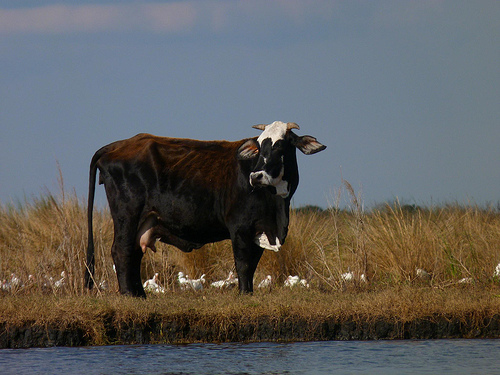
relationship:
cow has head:
[83, 122, 329, 301] [242, 121, 327, 186]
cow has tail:
[83, 122, 329, 301] [83, 145, 99, 294]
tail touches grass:
[83, 145, 99, 294] [0, 199, 499, 343]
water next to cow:
[6, 343, 498, 374] [83, 122, 329, 301]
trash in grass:
[260, 275, 311, 294] [0, 199, 499, 343]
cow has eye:
[83, 122, 329, 301] [274, 142, 289, 152]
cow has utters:
[83, 122, 329, 301] [132, 222, 159, 260]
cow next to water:
[83, 122, 329, 301] [6, 343, 498, 374]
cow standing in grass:
[83, 122, 329, 301] [0, 199, 499, 343]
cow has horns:
[83, 122, 329, 301] [248, 117, 301, 132]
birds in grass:
[146, 269, 239, 300] [0, 199, 499, 343]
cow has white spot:
[83, 122, 329, 301] [257, 126, 293, 143]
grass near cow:
[0, 199, 499, 343] [83, 122, 329, 301]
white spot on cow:
[257, 126, 293, 143] [83, 122, 329, 301]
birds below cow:
[146, 269, 239, 300] [83, 122, 329, 301]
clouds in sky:
[10, 6, 270, 37] [1, 6, 497, 204]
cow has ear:
[83, 122, 329, 301] [233, 137, 261, 164]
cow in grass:
[83, 122, 329, 301] [0, 199, 499, 343]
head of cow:
[242, 121, 327, 186] [83, 122, 329, 301]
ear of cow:
[233, 137, 261, 164] [83, 122, 329, 301]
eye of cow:
[274, 142, 289, 152] [83, 122, 329, 301]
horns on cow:
[248, 117, 301, 132] [83, 122, 329, 301]